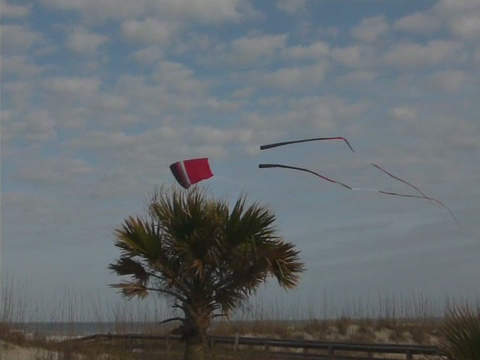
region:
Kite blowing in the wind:
[163, 131, 477, 212]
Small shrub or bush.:
[105, 188, 306, 346]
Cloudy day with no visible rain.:
[4, 6, 478, 129]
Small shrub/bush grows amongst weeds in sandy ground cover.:
[55, 184, 353, 355]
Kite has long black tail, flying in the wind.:
[253, 127, 462, 209]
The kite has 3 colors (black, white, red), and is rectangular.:
[164, 111, 471, 226]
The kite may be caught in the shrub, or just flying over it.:
[87, 125, 454, 353]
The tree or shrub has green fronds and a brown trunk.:
[100, 180, 310, 358]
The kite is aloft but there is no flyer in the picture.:
[153, 117, 467, 234]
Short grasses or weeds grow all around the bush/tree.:
[0, 277, 477, 358]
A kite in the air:
[163, 131, 458, 198]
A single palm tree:
[101, 185, 310, 349]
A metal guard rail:
[74, 330, 449, 358]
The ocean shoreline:
[11, 311, 165, 335]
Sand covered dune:
[225, 317, 462, 358]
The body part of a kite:
[165, 153, 216, 190]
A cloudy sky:
[10, 3, 471, 134]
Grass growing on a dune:
[218, 291, 475, 335]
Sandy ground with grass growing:
[5, 322, 470, 354]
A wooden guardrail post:
[227, 328, 248, 352]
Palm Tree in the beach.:
[105, 190, 309, 358]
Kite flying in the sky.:
[166, 134, 456, 217]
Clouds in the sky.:
[1, 1, 478, 138]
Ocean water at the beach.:
[10, 322, 111, 335]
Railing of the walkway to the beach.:
[81, 328, 445, 356]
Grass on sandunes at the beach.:
[224, 315, 478, 357]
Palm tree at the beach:
[102, 184, 302, 358]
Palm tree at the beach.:
[111, 182, 309, 358]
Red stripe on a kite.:
[185, 158, 213, 182]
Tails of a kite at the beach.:
[210, 132, 460, 223]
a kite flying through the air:
[156, 128, 429, 221]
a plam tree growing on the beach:
[108, 199, 300, 351]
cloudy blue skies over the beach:
[53, 63, 241, 130]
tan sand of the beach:
[5, 338, 44, 355]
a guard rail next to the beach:
[130, 325, 411, 358]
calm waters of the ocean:
[23, 323, 115, 336]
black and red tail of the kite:
[248, 127, 432, 207]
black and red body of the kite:
[159, 151, 226, 188]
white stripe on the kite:
[179, 158, 194, 187]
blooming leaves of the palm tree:
[121, 203, 271, 272]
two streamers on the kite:
[251, 121, 466, 243]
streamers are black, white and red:
[241, 133, 469, 213]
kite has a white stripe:
[166, 156, 219, 197]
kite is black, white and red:
[158, 138, 229, 193]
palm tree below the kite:
[111, 184, 305, 343]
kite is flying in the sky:
[133, 139, 465, 239]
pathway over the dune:
[245, 333, 434, 356]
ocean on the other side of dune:
[19, 307, 130, 336]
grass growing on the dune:
[272, 292, 477, 326]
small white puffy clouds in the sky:
[4, 4, 478, 137]